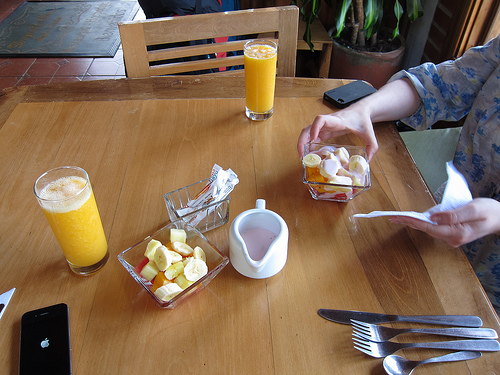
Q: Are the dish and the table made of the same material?
A: No, the dish is made of glass and the table is made of wood.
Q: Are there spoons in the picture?
A: Yes, there is a spoon.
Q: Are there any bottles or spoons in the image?
A: Yes, there is a spoon.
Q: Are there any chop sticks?
A: No, there are no chop sticks.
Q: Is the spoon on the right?
A: Yes, the spoon is on the right of the image.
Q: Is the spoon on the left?
A: No, the spoon is on the right of the image.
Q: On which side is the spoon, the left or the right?
A: The spoon is on the right of the image.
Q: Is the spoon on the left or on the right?
A: The spoon is on the right of the image.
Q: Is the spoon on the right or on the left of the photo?
A: The spoon is on the right of the image.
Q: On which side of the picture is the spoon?
A: The spoon is on the right of the image.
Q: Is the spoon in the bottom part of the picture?
A: Yes, the spoon is in the bottom of the image.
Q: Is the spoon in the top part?
A: No, the spoon is in the bottom of the image.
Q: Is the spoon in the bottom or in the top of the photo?
A: The spoon is in the bottom of the image.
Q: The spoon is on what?
A: The spoon is on the table.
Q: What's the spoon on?
A: The spoon is on the table.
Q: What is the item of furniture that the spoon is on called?
A: The piece of furniture is a table.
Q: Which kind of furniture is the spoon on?
A: The spoon is on the table.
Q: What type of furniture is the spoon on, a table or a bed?
A: The spoon is on a table.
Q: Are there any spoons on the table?
A: Yes, there is a spoon on the table.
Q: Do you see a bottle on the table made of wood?
A: No, there is a spoon on the table.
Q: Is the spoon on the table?
A: Yes, the spoon is on the table.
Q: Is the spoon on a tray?
A: No, the spoon is on the table.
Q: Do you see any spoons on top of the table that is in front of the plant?
A: Yes, there is a spoon on top of the table.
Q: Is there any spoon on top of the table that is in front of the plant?
A: Yes, there is a spoon on top of the table.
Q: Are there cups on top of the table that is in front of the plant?
A: No, there is a spoon on top of the table.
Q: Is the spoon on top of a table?
A: Yes, the spoon is on top of a table.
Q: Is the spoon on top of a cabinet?
A: No, the spoon is on top of a table.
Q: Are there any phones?
A: Yes, there is a phone.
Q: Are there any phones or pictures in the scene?
A: Yes, there is a phone.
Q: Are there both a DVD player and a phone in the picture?
A: No, there is a phone but no DVD players.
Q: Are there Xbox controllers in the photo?
A: No, there are no Xbox controllers.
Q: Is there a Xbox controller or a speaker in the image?
A: No, there are no Xbox controllers or speakers.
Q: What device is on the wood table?
A: The device is a phone.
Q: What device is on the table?
A: The device is a phone.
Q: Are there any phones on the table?
A: Yes, there is a phone on the table.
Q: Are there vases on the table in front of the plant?
A: No, there is a phone on the table.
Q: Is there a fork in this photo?
A: Yes, there is a fork.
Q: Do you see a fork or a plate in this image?
A: Yes, there is a fork.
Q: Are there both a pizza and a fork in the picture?
A: No, there is a fork but no pizzas.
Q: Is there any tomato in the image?
A: No, there are no tomatoes.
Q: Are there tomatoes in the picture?
A: No, there are no tomatoes.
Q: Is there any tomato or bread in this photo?
A: No, there are no tomatoes or breads.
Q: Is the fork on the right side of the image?
A: Yes, the fork is on the right of the image.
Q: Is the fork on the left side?
A: No, the fork is on the right of the image.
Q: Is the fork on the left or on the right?
A: The fork is on the right of the image.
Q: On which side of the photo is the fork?
A: The fork is on the right of the image.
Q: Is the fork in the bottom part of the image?
A: Yes, the fork is in the bottom of the image.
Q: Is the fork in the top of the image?
A: No, the fork is in the bottom of the image.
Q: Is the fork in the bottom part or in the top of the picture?
A: The fork is in the bottom of the image.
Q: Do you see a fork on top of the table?
A: Yes, there is a fork on top of the table.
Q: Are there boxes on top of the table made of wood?
A: No, there is a fork on top of the table.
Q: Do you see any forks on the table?
A: Yes, there is a fork on the table.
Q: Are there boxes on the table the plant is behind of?
A: No, there is a fork on the table.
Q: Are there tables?
A: Yes, there is a table.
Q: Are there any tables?
A: Yes, there is a table.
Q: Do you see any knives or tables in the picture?
A: Yes, there is a table.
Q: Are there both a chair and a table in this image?
A: Yes, there are both a table and a chair.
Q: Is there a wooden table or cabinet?
A: Yes, there is a wood table.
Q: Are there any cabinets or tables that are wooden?
A: Yes, the table is wooden.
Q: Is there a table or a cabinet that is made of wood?
A: Yes, the table is made of wood.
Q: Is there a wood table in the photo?
A: Yes, there is a wood table.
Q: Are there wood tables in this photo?
A: Yes, there is a wood table.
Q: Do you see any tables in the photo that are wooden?
A: Yes, there is a table that is wooden.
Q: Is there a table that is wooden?
A: Yes, there is a table that is wooden.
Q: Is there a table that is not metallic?
A: Yes, there is a wooden table.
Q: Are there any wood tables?
A: Yes, there is a table that is made of wood.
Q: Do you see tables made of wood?
A: Yes, there is a table that is made of wood.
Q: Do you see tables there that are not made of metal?
A: Yes, there is a table that is made of wood.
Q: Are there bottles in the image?
A: No, there are no bottles.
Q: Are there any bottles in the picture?
A: No, there are no bottles.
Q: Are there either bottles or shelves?
A: No, there are no bottles or shelves.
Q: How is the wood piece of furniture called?
A: The piece of furniture is a table.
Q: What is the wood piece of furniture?
A: The piece of furniture is a table.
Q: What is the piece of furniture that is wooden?
A: The piece of furniture is a table.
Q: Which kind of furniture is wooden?
A: The furniture is a table.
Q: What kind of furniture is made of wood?
A: The furniture is a table.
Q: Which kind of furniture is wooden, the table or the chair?
A: The table is wooden.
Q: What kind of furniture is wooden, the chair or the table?
A: The table is wooden.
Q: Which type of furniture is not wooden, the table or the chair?
A: The chair is not wooden.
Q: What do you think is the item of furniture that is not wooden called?
A: The piece of furniture is a chair.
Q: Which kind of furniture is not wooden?
A: The furniture is a chair.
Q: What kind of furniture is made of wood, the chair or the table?
A: The table is made of wood.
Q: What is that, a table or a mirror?
A: That is a table.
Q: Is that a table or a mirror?
A: That is a table.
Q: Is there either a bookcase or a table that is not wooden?
A: No, there is a table but it is wooden.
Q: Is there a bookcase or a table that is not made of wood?
A: No, there is a table but it is made of wood.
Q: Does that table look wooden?
A: Yes, the table is wooden.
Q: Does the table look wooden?
A: Yes, the table is wooden.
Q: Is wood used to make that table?
A: Yes, the table is made of wood.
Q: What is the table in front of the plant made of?
A: The table is made of wood.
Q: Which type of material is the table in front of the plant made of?
A: The table is made of wood.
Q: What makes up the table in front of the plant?
A: The table is made of wood.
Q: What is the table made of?
A: The table is made of wood.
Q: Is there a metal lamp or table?
A: No, there is a table but it is wooden.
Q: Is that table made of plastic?
A: No, the table is made of wood.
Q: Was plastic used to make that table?
A: No, the table is made of wood.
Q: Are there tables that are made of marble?
A: No, there is a table but it is made of wood.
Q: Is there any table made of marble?
A: No, there is a table but it is made of wood.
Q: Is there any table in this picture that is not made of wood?
A: No, there is a table but it is made of wood.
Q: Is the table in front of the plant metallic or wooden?
A: The table is wooden.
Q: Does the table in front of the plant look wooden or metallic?
A: The table is wooden.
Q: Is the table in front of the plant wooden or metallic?
A: The table is wooden.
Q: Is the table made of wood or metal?
A: The table is made of wood.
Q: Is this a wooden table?
A: Yes, this is a wooden table.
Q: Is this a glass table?
A: No, this is a wooden table.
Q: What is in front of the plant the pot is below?
A: The table is in front of the plant.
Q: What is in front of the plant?
A: The table is in front of the plant.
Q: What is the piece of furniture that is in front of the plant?
A: The piece of furniture is a table.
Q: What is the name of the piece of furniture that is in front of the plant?
A: The piece of furniture is a table.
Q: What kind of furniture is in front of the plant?
A: The piece of furniture is a table.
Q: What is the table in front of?
A: The table is in front of the plant.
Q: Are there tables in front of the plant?
A: Yes, there is a table in front of the plant.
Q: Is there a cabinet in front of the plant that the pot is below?
A: No, there is a table in front of the plant.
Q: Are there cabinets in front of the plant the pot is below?
A: No, there is a table in front of the plant.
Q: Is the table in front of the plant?
A: Yes, the table is in front of the plant.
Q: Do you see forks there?
A: Yes, there is a fork.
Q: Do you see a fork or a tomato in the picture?
A: Yes, there is a fork.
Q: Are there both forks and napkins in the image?
A: Yes, there are both a fork and a napkin.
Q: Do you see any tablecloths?
A: No, there are no tablecloths.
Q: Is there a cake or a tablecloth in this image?
A: No, there are no tablecloths or cakes.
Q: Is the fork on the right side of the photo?
A: Yes, the fork is on the right of the image.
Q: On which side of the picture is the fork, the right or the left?
A: The fork is on the right of the image.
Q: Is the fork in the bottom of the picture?
A: Yes, the fork is in the bottom of the image.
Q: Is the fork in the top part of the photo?
A: No, the fork is in the bottom of the image.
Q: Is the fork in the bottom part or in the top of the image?
A: The fork is in the bottom of the image.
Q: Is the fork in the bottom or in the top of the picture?
A: The fork is in the bottom of the image.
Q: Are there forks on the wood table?
A: Yes, there is a fork on the table.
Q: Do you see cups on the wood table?
A: No, there is a fork on the table.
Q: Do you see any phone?
A: Yes, there is a phone.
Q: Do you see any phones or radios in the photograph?
A: Yes, there is a phone.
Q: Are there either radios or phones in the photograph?
A: Yes, there is a phone.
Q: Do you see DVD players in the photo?
A: No, there are no DVD players.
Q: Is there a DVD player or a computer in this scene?
A: No, there are no DVD players or computers.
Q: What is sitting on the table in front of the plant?
A: The phone is sitting on the table.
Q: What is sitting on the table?
A: The phone is sitting on the table.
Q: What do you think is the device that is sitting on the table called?
A: The device is a phone.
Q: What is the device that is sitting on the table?
A: The device is a phone.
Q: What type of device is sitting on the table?
A: The device is a phone.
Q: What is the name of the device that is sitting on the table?
A: The device is a phone.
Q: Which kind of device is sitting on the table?
A: The device is a phone.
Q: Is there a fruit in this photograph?
A: Yes, there is a fruit.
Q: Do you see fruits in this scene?
A: Yes, there is a fruit.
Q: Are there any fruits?
A: Yes, there is a fruit.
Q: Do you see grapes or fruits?
A: Yes, there is a fruit.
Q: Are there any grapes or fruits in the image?
A: Yes, there is a fruit.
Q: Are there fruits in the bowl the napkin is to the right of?
A: Yes, there is a fruit in the bowl.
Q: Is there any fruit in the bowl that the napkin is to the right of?
A: Yes, there is a fruit in the bowl.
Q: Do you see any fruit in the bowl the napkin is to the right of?
A: Yes, there is a fruit in the bowl.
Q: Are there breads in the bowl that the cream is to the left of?
A: No, there is a fruit in the bowl.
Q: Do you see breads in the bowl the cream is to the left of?
A: No, there is a fruit in the bowl.